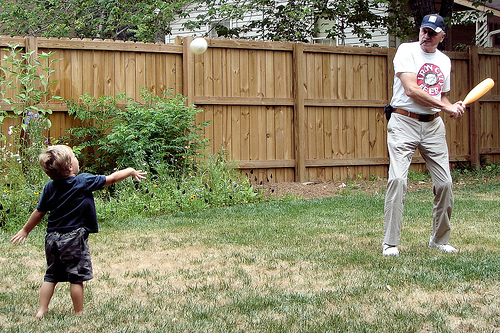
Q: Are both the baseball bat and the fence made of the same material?
A: No, the baseball bat is made of plastic and the fence is made of wood.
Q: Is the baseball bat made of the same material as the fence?
A: No, the baseball bat is made of plastic and the fence is made of wood.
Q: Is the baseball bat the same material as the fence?
A: No, the baseball bat is made of plastic and the fence is made of wood.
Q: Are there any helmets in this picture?
A: No, there are no helmets.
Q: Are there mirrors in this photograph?
A: No, there are no mirrors.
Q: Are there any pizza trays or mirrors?
A: No, there are no mirrors or pizza trays.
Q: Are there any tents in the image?
A: No, there are no tents.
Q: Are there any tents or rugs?
A: No, there are no tents or rugs.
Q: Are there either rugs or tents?
A: No, there are no tents or rugs.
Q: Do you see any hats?
A: Yes, there is a hat.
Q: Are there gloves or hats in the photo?
A: Yes, there is a hat.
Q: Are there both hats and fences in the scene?
A: Yes, there are both a hat and a fence.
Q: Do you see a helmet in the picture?
A: No, there are no helmets.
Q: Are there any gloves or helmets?
A: No, there are no helmets or gloves.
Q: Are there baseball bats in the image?
A: Yes, there is a baseball bat.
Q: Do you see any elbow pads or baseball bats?
A: Yes, there is a baseball bat.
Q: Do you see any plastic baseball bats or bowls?
A: Yes, there is a plastic baseball bat.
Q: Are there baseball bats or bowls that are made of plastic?
A: Yes, the baseball bat is made of plastic.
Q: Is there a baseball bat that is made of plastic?
A: Yes, there is a baseball bat that is made of plastic.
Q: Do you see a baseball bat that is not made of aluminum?
A: Yes, there is a baseball bat that is made of plastic.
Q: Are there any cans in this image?
A: No, there are no cans.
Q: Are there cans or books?
A: No, there are no cans or books.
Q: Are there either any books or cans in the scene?
A: No, there are no cans or books.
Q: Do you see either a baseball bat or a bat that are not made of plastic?
A: No, there is a baseball bat but it is made of plastic.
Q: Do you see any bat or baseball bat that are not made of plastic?
A: No, there is a baseball bat but it is made of plastic.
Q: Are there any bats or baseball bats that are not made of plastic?
A: No, there is a baseball bat but it is made of plastic.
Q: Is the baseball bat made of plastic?
A: Yes, the baseball bat is made of plastic.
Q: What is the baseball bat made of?
A: The baseball bat is made of plastic.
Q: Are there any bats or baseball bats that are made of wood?
A: No, there is a baseball bat but it is made of plastic.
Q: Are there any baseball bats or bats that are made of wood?
A: No, there is a baseball bat but it is made of plastic.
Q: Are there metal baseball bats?
A: No, there is a baseball bat but it is made of plastic.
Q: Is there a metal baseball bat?
A: No, there is a baseball bat but it is made of plastic.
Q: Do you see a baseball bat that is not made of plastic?
A: No, there is a baseball bat but it is made of plastic.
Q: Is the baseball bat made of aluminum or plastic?
A: The baseball bat is made of plastic.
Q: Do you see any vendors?
A: No, there are no vendors.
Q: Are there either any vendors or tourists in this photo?
A: No, there are no vendors or tourists.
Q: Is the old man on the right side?
A: Yes, the man is on the right of the image.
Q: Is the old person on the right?
A: Yes, the man is on the right of the image.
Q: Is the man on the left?
A: No, the man is on the right of the image.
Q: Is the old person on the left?
A: No, the man is on the right of the image.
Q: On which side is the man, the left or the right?
A: The man is on the right of the image.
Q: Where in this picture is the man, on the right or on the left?
A: The man is on the right of the image.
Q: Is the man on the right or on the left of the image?
A: The man is on the right of the image.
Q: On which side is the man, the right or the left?
A: The man is on the right of the image.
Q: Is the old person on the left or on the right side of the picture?
A: The man is on the right of the image.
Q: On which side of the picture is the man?
A: The man is on the right of the image.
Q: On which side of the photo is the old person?
A: The man is on the right of the image.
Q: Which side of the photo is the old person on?
A: The man is on the right of the image.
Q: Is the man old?
A: Yes, the man is old.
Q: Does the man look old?
A: Yes, the man is old.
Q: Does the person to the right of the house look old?
A: Yes, the man is old.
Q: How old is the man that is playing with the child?
A: The man is old.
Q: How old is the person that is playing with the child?
A: The man is old.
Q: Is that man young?
A: No, the man is old.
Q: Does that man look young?
A: No, the man is old.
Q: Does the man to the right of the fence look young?
A: No, the man is old.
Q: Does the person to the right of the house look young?
A: No, the man is old.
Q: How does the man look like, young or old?
A: The man is old.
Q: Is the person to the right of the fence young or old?
A: The man is old.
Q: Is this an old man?
A: Yes, this is an old man.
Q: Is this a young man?
A: No, this is an old man.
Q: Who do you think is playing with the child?
A: The man is playing with the child.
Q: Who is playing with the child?
A: The man is playing with the child.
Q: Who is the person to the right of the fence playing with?
A: The man is playing with the child.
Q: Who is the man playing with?
A: The man is playing with the child.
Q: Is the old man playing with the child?
A: Yes, the man is playing with the child.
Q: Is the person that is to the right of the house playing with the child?
A: Yes, the man is playing with the child.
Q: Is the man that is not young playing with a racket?
A: No, the man is playing with the child.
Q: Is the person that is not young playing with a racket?
A: No, the man is playing with the child.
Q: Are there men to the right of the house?
A: Yes, there is a man to the right of the house.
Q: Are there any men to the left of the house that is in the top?
A: No, the man is to the right of the house.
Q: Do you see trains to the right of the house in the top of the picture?
A: No, there is a man to the right of the house.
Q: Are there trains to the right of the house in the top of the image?
A: No, there is a man to the right of the house.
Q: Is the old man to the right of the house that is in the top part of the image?
A: Yes, the man is to the right of the house.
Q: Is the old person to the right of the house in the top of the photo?
A: Yes, the man is to the right of the house.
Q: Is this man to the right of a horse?
A: No, the man is to the right of the house.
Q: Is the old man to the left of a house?
A: No, the man is to the right of a house.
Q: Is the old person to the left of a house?
A: No, the man is to the right of a house.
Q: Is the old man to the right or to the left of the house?
A: The man is to the right of the house.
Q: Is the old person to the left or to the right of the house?
A: The man is to the right of the house.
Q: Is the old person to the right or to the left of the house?
A: The man is to the right of the house.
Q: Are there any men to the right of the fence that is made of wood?
A: Yes, there is a man to the right of the fence.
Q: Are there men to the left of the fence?
A: No, the man is to the right of the fence.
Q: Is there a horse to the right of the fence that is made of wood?
A: No, there is a man to the right of the fence.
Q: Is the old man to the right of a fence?
A: Yes, the man is to the right of a fence.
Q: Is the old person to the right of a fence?
A: Yes, the man is to the right of a fence.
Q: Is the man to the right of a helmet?
A: No, the man is to the right of a fence.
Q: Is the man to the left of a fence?
A: No, the man is to the right of a fence.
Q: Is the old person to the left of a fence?
A: No, the man is to the right of a fence.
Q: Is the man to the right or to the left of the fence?
A: The man is to the right of the fence.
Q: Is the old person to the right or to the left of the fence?
A: The man is to the right of the fence.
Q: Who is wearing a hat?
A: The man is wearing a hat.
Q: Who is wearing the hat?
A: The man is wearing a hat.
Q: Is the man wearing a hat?
A: Yes, the man is wearing a hat.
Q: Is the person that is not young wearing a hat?
A: Yes, the man is wearing a hat.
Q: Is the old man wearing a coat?
A: No, the man is wearing a hat.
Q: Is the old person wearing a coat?
A: No, the man is wearing a hat.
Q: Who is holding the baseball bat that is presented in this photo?
A: The man is holding the baseball bat.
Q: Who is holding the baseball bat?
A: The man is holding the baseball bat.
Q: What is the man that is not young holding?
A: The man is holding the baseball bat.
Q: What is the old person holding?
A: The man is holding the baseball bat.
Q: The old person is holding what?
A: The man is holding the baseball bat.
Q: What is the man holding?
A: The man is holding the baseball bat.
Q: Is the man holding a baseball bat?
A: Yes, the man is holding a baseball bat.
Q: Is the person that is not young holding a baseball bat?
A: Yes, the man is holding a baseball bat.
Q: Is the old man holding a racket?
A: No, the man is holding a baseball bat.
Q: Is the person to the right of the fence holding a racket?
A: No, the man is holding a baseball bat.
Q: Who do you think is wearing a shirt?
A: The man is wearing a shirt.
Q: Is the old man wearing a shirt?
A: Yes, the man is wearing a shirt.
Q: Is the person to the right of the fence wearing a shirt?
A: Yes, the man is wearing a shirt.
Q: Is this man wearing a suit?
A: No, the man is wearing a shirt.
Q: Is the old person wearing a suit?
A: No, the man is wearing a shirt.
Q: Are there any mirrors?
A: No, there are no mirrors.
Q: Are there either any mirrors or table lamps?
A: No, there are no mirrors or table lamps.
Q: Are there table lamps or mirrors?
A: No, there are no mirrors or table lamps.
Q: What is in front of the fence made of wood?
A: The bushes are in front of the fence.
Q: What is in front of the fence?
A: The bushes are in front of the fence.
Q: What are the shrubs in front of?
A: The shrubs are in front of the fence.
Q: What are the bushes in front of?
A: The shrubs are in front of the fence.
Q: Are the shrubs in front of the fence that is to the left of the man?
A: Yes, the shrubs are in front of the fence.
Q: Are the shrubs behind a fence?
A: No, the shrubs are in front of a fence.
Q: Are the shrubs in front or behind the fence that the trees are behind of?
A: The shrubs are in front of the fence.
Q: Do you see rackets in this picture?
A: No, there are no rackets.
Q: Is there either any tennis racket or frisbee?
A: No, there are no rackets or frisbees.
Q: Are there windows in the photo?
A: Yes, there is a window.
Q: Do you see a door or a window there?
A: Yes, there is a window.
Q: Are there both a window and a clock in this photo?
A: No, there is a window but no clocks.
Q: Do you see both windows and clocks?
A: No, there is a window but no clocks.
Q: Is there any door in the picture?
A: No, there are no doors.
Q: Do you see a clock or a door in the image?
A: No, there are no doors or clocks.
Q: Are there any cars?
A: No, there are no cars.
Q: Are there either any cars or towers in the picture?
A: No, there are no cars or towers.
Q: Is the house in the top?
A: Yes, the house is in the top of the image.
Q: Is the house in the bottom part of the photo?
A: No, the house is in the top of the image.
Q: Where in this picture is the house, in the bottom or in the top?
A: The house is in the top of the image.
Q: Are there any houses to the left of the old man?
A: Yes, there is a house to the left of the man.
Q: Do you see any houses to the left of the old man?
A: Yes, there is a house to the left of the man.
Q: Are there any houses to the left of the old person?
A: Yes, there is a house to the left of the man.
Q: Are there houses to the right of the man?
A: No, the house is to the left of the man.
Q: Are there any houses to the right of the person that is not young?
A: No, the house is to the left of the man.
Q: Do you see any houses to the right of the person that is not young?
A: No, the house is to the left of the man.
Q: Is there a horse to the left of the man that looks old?
A: No, there is a house to the left of the man.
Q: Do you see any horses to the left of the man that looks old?
A: No, there is a house to the left of the man.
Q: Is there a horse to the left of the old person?
A: No, there is a house to the left of the man.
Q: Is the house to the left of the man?
A: Yes, the house is to the left of the man.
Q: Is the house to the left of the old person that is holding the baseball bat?
A: Yes, the house is to the left of the man.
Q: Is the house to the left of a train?
A: No, the house is to the left of the man.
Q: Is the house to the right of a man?
A: No, the house is to the left of a man.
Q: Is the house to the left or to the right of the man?
A: The house is to the left of the man.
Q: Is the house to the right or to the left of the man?
A: The house is to the left of the man.